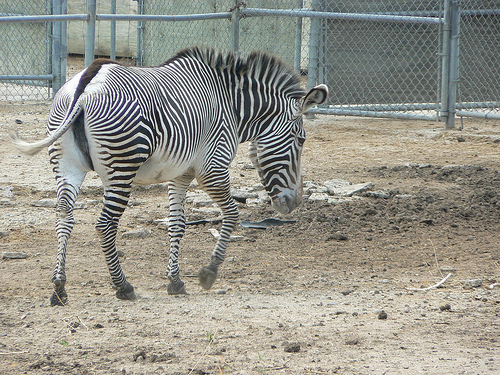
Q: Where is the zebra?
A: In a pen.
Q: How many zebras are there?
A: One.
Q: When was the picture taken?
A: During the day.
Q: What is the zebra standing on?
A: Dirt.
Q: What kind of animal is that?
A: Zebra.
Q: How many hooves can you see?
A: Four.